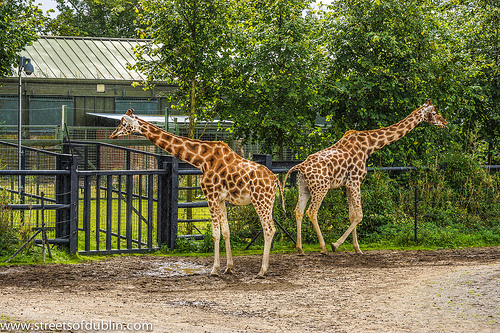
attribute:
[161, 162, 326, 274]
fur — brown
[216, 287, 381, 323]
sand — brown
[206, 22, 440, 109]
leaves — green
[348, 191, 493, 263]
grass — green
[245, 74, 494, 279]
giraffe — tall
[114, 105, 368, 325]
giraffe — tall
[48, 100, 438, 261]
fence — wooden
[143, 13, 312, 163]
tree — green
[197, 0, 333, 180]
tree — green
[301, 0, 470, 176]
tree — green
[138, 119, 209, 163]
neck — long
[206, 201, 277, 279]
legs — long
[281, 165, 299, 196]
tail — thin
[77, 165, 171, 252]
gate — closed, metallic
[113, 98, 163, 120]
window — closed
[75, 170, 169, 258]
gate — metal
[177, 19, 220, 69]
leaves — green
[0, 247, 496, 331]
ground — muddy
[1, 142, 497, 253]
fence — grey, metal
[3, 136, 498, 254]
gate — Grey colored, metal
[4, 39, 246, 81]
roof — tinned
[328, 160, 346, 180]
spots — brown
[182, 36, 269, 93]
leaves — green